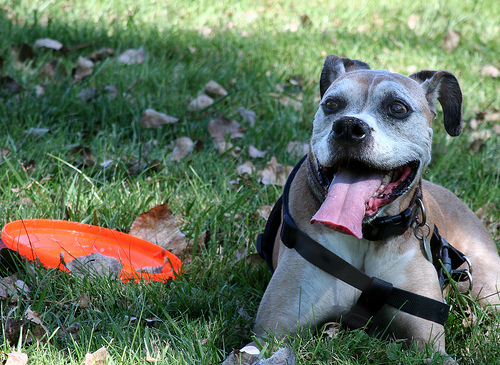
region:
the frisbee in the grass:
[5, 205, 192, 302]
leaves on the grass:
[80, 39, 255, 197]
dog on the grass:
[247, 41, 498, 332]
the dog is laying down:
[232, 38, 497, 361]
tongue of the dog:
[304, 178, 382, 251]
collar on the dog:
[371, 203, 412, 247]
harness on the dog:
[270, 216, 464, 331]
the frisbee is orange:
[0, 211, 177, 297]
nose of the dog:
[312, 104, 391, 151]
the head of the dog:
[300, 47, 473, 229]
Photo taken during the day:
[7, 0, 482, 359]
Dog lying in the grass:
[277, 49, 479, 351]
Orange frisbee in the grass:
[10, 207, 197, 293]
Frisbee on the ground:
[2, 198, 187, 295]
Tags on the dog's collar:
[412, 214, 442, 266]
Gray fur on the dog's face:
[304, 63, 426, 231]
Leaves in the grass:
[35, 15, 289, 351]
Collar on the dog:
[291, 165, 428, 247]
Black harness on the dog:
[230, 184, 457, 331]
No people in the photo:
[0, 11, 498, 357]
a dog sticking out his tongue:
[208, 45, 494, 362]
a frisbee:
[0, 210, 185, 290]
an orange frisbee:
[0, 215, 185, 285]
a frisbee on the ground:
[0, 211, 185, 291]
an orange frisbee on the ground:
[0, 215, 189, 292]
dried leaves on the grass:
[2, 35, 279, 183]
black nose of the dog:
[328, 114, 371, 143]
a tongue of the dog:
[306, 178, 380, 245]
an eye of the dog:
[378, 95, 414, 120]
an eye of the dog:
[318, 95, 343, 114]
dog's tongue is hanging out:
[310, 174, 378, 237]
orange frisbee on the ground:
[3, 218, 180, 283]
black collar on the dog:
[370, 211, 423, 236]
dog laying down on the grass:
[240, 57, 499, 359]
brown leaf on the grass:
[129, 203, 184, 255]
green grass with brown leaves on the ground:
[4, 3, 494, 363]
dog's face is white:
[309, 78, 426, 164]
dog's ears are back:
[311, 54, 462, 134]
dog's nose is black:
[331, 115, 370, 140]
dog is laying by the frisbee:
[2, 52, 498, 358]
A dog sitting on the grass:
[230, 49, 498, 361]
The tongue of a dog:
[308, 168, 385, 241]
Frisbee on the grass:
[2, 207, 184, 297]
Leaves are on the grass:
[1, 1, 499, 363]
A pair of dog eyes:
[318, 86, 413, 121]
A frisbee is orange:
[1, 213, 187, 289]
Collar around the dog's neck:
[361, 175, 429, 246]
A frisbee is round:
[1, 208, 185, 286]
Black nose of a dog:
[328, 113, 372, 150]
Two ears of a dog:
[310, 45, 468, 145]